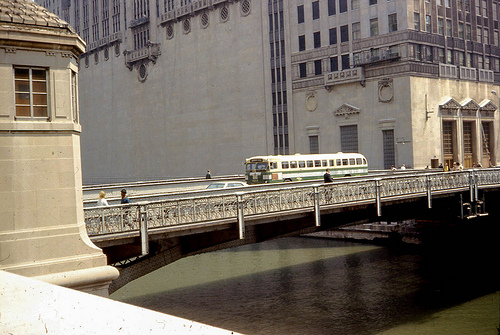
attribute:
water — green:
[272, 269, 409, 310]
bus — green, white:
[230, 144, 373, 181]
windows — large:
[283, 158, 366, 170]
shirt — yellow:
[443, 165, 448, 171]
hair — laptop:
[101, 191, 106, 198]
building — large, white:
[4, 4, 88, 193]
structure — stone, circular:
[189, 24, 411, 143]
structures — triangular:
[10, 6, 83, 58]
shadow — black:
[363, 230, 402, 263]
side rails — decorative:
[202, 194, 283, 214]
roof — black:
[15, 6, 40, 21]